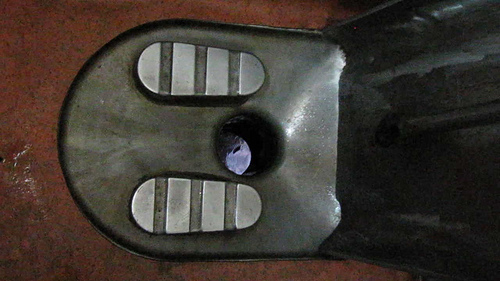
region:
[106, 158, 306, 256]
the footrest is steel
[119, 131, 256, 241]
the footrest is steel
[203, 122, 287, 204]
the center item is blue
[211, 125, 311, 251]
the center item is blue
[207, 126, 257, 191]
the center item is blue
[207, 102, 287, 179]
hole in the ground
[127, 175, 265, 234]
left foot goes here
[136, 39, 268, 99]
right foot goes here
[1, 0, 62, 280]
floor is red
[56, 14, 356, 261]
toilet bowl is on the floor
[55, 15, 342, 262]
toilet is made of metal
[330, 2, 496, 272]
panel behind toilet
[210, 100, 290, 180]
hole is empty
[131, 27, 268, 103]
three groove are visible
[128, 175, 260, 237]
three groove are visible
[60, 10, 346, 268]
metal object on brown floor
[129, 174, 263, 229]
oval shaped object on metal object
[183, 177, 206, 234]
groove on metal object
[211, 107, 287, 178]
circle in metal object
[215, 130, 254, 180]
white bottom of circle on metal object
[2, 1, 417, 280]
brown floor underneate metal object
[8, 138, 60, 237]
white scratches on brown floor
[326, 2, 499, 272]
dark gray portion of metal object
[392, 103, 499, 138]
groove on dark gray part of metal object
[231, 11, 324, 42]
edging around metal object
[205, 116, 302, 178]
round hold in the floor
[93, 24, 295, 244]
two silver shoe outlines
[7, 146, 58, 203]
water on the ground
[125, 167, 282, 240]
place to put foot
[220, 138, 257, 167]
water shining from the bottom of the hole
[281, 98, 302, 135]
light reflecting on the ground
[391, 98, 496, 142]
black pipe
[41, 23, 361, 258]
silver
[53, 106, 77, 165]
black line outlining the silver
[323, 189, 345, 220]
shiny silver